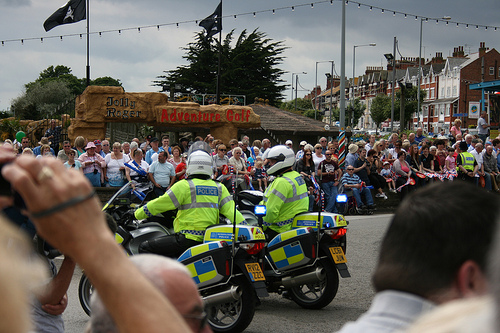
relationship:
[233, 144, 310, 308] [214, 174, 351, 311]
motorcyclist on bikes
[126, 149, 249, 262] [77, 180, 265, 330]
man on motorcycle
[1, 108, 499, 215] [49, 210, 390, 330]
spectators lining street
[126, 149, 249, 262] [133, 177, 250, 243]
man wearing coat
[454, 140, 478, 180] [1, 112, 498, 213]
man facing crowd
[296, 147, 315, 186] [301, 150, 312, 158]
woman wearing sunglasses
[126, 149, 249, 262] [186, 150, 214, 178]
man wearing helmet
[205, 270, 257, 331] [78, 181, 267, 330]
wheel on bike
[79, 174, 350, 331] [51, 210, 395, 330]
bikes on concrete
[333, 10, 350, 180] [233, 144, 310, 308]
pole near motorcyclist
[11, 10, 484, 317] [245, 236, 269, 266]
picture of a stop sign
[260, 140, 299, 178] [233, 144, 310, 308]
head of a motorcyclist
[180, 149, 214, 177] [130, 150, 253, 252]
head of a person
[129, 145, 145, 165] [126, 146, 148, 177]
head of a person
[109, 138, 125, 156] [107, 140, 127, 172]
head of a person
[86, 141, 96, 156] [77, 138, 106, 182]
head of a person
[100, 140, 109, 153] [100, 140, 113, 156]
head of a person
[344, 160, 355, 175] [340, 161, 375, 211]
head of a person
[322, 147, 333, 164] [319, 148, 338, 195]
head of a person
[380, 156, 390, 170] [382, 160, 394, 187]
head of a person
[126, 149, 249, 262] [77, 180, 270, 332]
man on a bike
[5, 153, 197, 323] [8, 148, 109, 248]
person with a strap around hand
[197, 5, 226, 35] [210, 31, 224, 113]
flag on pole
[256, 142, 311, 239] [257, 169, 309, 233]
motorcyclist wearing jacket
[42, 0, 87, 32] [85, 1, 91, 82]
flag hanging from pole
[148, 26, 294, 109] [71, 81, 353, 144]
pines standing behind store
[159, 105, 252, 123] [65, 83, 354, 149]
sign painted on store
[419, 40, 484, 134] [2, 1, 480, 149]
house standing in background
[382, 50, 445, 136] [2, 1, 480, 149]
house standing in background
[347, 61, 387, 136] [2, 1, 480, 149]
house standing in background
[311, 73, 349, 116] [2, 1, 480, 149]
house standing in background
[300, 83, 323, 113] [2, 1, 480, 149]
house standing in background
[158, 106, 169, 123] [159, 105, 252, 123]
letter forming sign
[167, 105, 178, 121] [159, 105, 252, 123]
letter forming sign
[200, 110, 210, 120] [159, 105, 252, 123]
letter forming sign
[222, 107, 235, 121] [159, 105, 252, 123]
letter forming sign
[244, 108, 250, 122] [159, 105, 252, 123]
letter forming sign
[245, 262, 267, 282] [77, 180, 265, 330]
license mounted on motorcycle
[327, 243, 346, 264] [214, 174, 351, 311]
license plate mounted on bikes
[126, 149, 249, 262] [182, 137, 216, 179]
man wearing helmet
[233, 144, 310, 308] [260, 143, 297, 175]
motorcyclist wearing helmet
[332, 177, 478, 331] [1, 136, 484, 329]
man standing in forefront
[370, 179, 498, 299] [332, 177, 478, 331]
hair belonging to man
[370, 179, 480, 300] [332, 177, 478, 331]
hair belonging to man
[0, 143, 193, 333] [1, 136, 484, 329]
person standing in forefront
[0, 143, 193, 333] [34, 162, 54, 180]
person wearing ring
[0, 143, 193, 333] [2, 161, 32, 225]
person holding camera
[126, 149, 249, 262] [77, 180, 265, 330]
man sitting on top of motorcycle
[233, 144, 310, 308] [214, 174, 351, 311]
motorcyclist sitting on top of bikes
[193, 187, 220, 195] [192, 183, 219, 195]
police printed on patch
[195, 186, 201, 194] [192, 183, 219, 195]
letter printed on patch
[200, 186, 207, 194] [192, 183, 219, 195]
letter printed on patch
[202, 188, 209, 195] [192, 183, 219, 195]
letter printed on patch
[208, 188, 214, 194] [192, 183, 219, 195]
letter printed on patch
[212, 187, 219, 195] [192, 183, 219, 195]
letter printed on patch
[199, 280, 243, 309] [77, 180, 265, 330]
tailpipe mounted on motorcycle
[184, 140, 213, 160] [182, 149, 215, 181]
visor attached to helmet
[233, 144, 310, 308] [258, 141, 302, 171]
motorcyclist wearing helmet